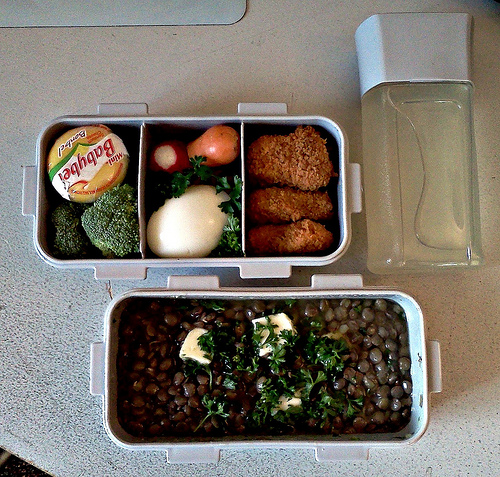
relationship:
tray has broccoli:
[55, 247, 137, 300] [74, 198, 162, 265]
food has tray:
[83, 120, 327, 246] [55, 247, 137, 300]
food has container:
[83, 120, 327, 246] [21, 100, 364, 279]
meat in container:
[250, 132, 311, 182] [111, 95, 285, 152]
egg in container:
[158, 178, 252, 232] [111, 95, 285, 152]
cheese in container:
[55, 73, 126, 184] [111, 95, 285, 152]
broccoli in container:
[74, 198, 162, 265] [111, 95, 285, 152]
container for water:
[325, 23, 496, 231] [372, 123, 454, 161]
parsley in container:
[217, 175, 247, 234] [21, 100, 364, 279]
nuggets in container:
[248, 81, 324, 252] [21, 100, 364, 279]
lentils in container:
[119, 327, 273, 414] [21, 100, 364, 279]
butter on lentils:
[181, 341, 351, 359] [119, 327, 273, 414]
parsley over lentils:
[217, 175, 247, 234] [119, 327, 273, 414]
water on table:
[372, 123, 454, 161] [101, 40, 272, 102]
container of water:
[325, 23, 496, 231] [372, 123, 454, 161]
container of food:
[111, 95, 285, 152] [83, 120, 327, 246]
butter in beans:
[181, 341, 351, 359] [133, 316, 204, 441]